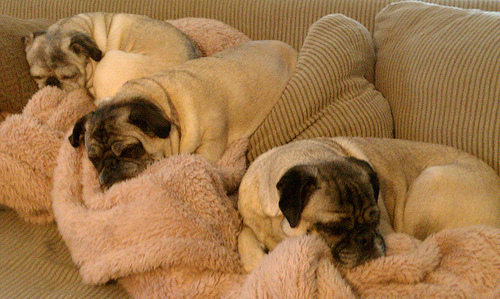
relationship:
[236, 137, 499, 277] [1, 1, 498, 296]
dog on top of a couch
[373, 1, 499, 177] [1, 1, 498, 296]
pillow on top of a couch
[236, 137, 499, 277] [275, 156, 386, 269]
dog has head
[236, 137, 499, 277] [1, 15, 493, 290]
dog on top of a blanket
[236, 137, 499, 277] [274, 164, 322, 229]
dog has ear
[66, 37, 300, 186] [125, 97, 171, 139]
dog has ear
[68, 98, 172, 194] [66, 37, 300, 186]
head of dog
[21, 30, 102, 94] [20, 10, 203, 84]
head of dog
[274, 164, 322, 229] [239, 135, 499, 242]
ear of dog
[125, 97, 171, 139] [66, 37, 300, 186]
ear of dog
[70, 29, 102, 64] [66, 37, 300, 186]
ear of dog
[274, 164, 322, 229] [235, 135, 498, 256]
ear of dog